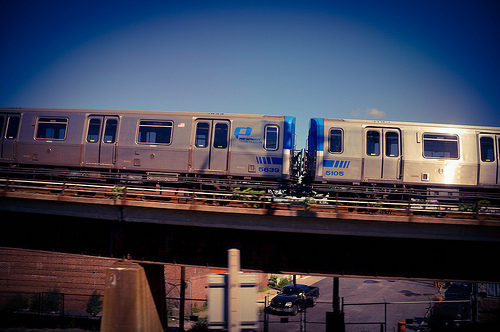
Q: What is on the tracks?
A: A train.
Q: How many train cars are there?
A: 2.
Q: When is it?
A: Daytime.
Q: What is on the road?
A: Cars.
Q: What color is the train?
A: Silver.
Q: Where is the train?
A: On the tracks.